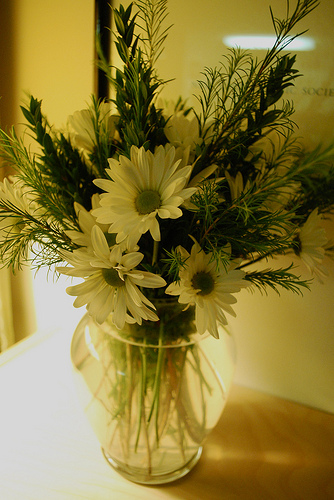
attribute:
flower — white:
[163, 238, 251, 338]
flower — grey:
[88, 140, 201, 249]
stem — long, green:
[155, 222, 175, 320]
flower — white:
[77, 143, 206, 253]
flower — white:
[170, 227, 258, 349]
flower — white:
[48, 224, 171, 340]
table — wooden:
[4, 315, 331, 499]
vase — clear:
[91, 323, 207, 402]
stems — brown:
[162, 323, 198, 469]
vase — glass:
[68, 308, 237, 486]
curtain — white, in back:
[0, 142, 49, 338]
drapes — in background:
[11, 248, 53, 330]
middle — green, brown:
[56, 155, 203, 287]